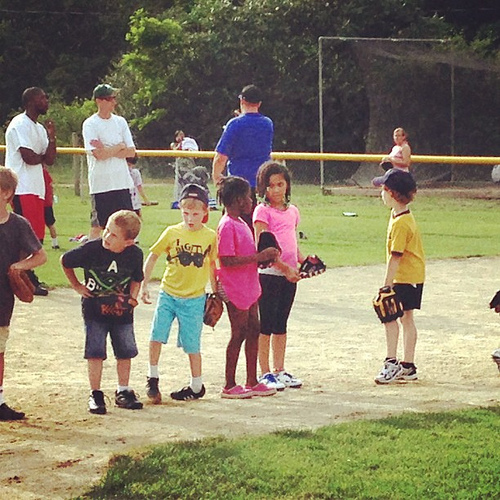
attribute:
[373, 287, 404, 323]
baseball glove —  for baseball,  leather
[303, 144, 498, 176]
pole — yellow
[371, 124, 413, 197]
woman —  seated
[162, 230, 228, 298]
yellow shirt —  yellow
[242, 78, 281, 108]
cap — black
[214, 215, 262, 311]
shirt — pink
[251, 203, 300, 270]
shirt — pink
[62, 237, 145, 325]
t-shirt — dark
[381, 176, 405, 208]
ground — yellow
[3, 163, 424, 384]
children —   in  line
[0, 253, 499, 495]
dirt path — of dirt,  flat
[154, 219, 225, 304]
shirt — yellow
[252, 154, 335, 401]
girl —  talking,  in pink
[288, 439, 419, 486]
grass —  green 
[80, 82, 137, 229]
adult —  Two 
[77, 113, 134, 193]
shirt —  white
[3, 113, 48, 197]
shirt —  white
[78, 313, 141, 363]
jean shorts —  A pair,  jeans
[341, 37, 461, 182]
tree trunk —   tree's,  large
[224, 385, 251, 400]
pink shoes —   pair,  pink 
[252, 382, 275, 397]
pink shoes —  pink 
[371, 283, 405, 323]
gloves —  hand's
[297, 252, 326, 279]
gloves —  hand's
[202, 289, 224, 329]
gloves —  hand's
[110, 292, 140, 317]
gloves —  hand's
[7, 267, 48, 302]
gloves —  hand's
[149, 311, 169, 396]
leg —  upturned,  his 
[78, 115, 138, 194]
shirt —  his,  white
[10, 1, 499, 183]
trees —   full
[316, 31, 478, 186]
metal frame —  metal 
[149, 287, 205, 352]
shorts — blue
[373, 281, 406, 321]
glove — black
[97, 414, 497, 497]
area —  grassy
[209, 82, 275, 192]
man —  talking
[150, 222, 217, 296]
jersey —  yellow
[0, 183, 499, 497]
field —  for baseball